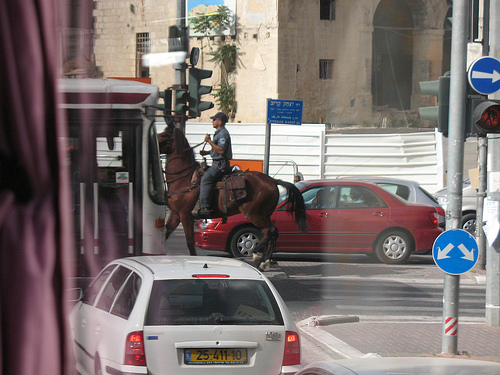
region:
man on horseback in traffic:
[149, 102, 293, 269]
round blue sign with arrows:
[427, 227, 481, 278]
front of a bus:
[57, 70, 172, 273]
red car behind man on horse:
[187, 148, 439, 273]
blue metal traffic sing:
[265, 98, 306, 126]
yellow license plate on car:
[182, 347, 252, 364]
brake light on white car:
[278, 332, 303, 364]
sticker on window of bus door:
[114, 170, 131, 185]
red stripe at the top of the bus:
[64, 83, 151, 110]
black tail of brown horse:
[267, 170, 319, 237]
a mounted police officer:
[153, 108, 314, 272]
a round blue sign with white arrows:
[425, 225, 485, 274]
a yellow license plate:
[182, 345, 254, 364]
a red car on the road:
[203, 172, 450, 273]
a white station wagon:
[80, 252, 309, 373]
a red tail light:
[280, 327, 308, 371]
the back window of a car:
[148, 280, 272, 325]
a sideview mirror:
[68, 282, 80, 302]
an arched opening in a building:
[364, 6, 435, 123]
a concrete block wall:
[92, 4, 166, 78]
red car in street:
[198, 165, 443, 267]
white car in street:
[66, 251, 311, 370]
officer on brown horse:
[143, 106, 307, 256]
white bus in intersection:
[42, 68, 186, 290]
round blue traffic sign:
[429, 227, 480, 278]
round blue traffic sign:
[463, 57, 498, 93]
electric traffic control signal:
[180, 62, 214, 122]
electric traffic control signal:
[168, 81, 187, 115]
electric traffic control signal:
[408, 69, 450, 131]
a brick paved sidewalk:
[323, 314, 496, 359]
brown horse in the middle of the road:
[162, 114, 274, 259]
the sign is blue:
[342, 151, 477, 242]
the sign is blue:
[370, 87, 496, 259]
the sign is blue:
[384, 136, 497, 361]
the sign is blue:
[405, 151, 460, 250]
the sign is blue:
[409, 177, 485, 269]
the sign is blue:
[416, 221, 480, 305]